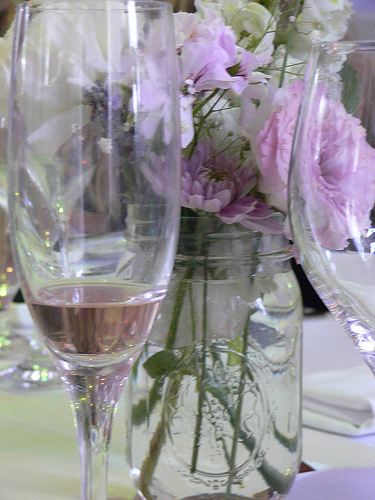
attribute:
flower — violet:
[256, 79, 373, 253]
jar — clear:
[181, 235, 307, 460]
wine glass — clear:
[32, 183, 131, 244]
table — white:
[22, 469, 69, 498]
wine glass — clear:
[326, 186, 362, 205]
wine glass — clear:
[4, 277, 16, 298]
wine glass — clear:
[28, 349, 39, 369]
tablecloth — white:
[335, 487, 364, 499]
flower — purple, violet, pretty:
[190, 165, 243, 200]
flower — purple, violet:
[184, 42, 214, 67]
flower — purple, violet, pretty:
[267, 131, 280, 162]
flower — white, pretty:
[226, 7, 247, 21]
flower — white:
[312, 4, 340, 25]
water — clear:
[173, 470, 184, 489]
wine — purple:
[88, 327, 115, 342]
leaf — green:
[154, 359, 167, 369]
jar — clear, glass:
[244, 266, 275, 311]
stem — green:
[172, 302, 179, 324]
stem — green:
[206, 295, 211, 336]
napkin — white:
[328, 383, 349, 408]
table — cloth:
[2, 306, 373, 498]